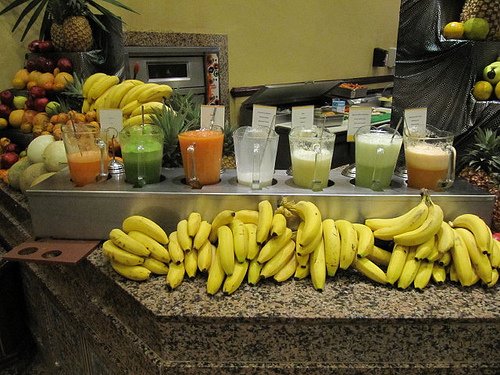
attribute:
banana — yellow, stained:
[282, 199, 319, 248]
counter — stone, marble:
[58, 239, 499, 319]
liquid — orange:
[183, 131, 225, 186]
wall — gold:
[0, 1, 401, 92]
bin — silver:
[27, 164, 496, 241]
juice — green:
[122, 144, 164, 182]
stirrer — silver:
[255, 113, 278, 177]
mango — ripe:
[26, 84, 54, 99]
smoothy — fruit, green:
[289, 151, 334, 190]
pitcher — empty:
[229, 123, 278, 188]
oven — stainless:
[124, 48, 212, 126]